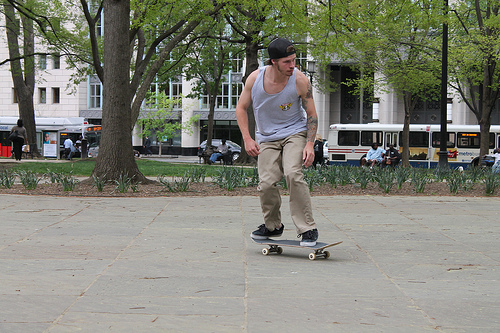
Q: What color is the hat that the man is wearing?
A: Black.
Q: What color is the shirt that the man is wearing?
A: Gray.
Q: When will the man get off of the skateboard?
A: When he gets tired.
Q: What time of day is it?
A: Daytime.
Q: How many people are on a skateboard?
A: One.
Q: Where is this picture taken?
A: On a public sidewalk.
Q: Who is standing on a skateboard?
A: A man.